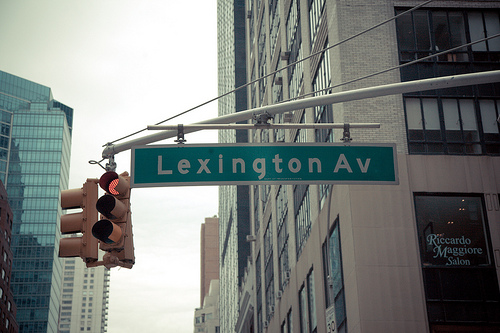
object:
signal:
[99, 170, 128, 197]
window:
[416, 192, 493, 266]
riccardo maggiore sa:
[428, 233, 482, 264]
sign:
[131, 143, 400, 186]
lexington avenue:
[156, 152, 371, 177]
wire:
[89, 155, 108, 170]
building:
[242, 2, 499, 330]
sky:
[2, 1, 221, 68]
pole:
[102, 67, 495, 159]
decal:
[428, 232, 484, 265]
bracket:
[174, 139, 186, 144]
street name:
[157, 154, 370, 173]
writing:
[157, 155, 173, 175]